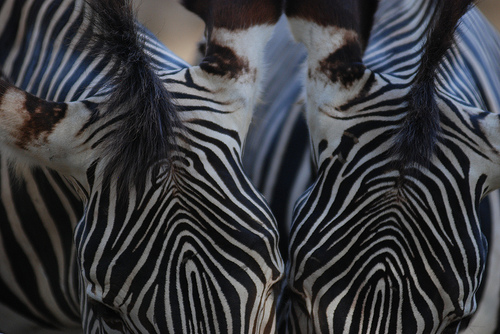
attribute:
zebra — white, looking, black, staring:
[36, 48, 274, 332]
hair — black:
[111, 82, 190, 159]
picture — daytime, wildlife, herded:
[10, 6, 495, 319]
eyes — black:
[68, 274, 145, 331]